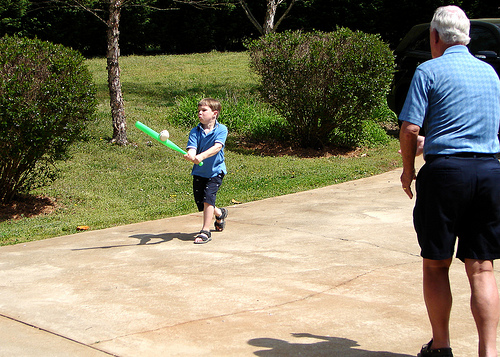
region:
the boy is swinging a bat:
[120, 85, 395, 316]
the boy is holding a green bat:
[110, 74, 354, 298]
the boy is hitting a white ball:
[162, 99, 184, 171]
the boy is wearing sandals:
[187, 220, 306, 288]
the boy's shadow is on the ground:
[97, 196, 204, 251]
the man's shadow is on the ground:
[233, 290, 340, 353]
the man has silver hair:
[436, 8, 494, 75]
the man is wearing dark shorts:
[397, 160, 492, 270]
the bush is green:
[10, 28, 210, 264]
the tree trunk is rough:
[96, 22, 186, 203]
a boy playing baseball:
[135, 99, 230, 241]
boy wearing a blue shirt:
[185, 125, 226, 175]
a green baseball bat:
[134, 119, 204, 164]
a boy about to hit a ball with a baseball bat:
[137, 97, 229, 244]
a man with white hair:
[428, 4, 470, 51]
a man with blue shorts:
[411, 154, 498, 264]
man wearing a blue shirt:
[399, 45, 499, 152]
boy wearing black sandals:
[194, 207, 226, 244]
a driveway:
[0, 150, 499, 355]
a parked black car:
[391, 17, 498, 116]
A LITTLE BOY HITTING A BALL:
[131, 96, 230, 248]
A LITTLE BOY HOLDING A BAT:
[134, 96, 232, 245]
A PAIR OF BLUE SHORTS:
[409, 149, 499, 265]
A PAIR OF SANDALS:
[191, 205, 229, 245]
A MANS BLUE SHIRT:
[396, 42, 498, 157]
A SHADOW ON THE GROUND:
[244, 327, 412, 354]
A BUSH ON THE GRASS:
[246, 25, 402, 159]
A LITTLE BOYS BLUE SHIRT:
[185, 121, 230, 182]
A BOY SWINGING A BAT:
[129, 94, 231, 247]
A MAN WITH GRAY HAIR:
[393, 4, 498, 354]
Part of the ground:
[193, 274, 254, 309]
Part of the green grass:
[96, 182, 139, 211]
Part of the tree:
[108, 46, 118, 85]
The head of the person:
[195, 96, 222, 126]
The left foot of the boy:
[191, 227, 211, 246]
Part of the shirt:
[440, 92, 467, 122]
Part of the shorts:
[427, 197, 443, 232]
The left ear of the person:
[429, 24, 441, 48]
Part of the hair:
[447, 21, 458, 32]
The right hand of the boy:
[183, 147, 196, 163]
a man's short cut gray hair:
[430, 5, 472, 46]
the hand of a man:
[392, 167, 422, 194]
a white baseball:
[155, 130, 175, 142]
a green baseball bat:
[131, 118, 205, 168]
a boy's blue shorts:
[188, 170, 223, 212]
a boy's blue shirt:
[185, 120, 228, 178]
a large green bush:
[251, 23, 396, 148]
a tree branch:
[102, 3, 137, 143]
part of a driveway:
[0, 149, 496, 354]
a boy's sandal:
[193, 228, 214, 243]